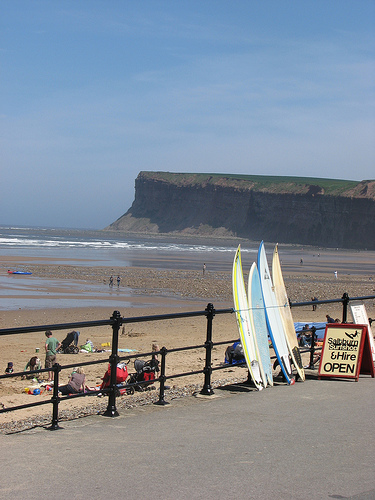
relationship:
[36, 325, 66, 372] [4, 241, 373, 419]
man on beach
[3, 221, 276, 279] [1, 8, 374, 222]
water under sky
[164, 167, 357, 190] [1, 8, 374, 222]
grass under sky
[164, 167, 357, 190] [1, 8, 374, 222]
grass below sky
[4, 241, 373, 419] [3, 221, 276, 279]
beach close to water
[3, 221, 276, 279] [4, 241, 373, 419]
water next to beach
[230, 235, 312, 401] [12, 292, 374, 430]
surfboards on rails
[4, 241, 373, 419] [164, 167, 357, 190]
beach below grass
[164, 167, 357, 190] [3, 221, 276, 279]
grass above water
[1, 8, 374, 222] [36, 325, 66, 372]
sky above man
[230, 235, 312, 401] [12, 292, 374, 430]
surfboards leaning on rails